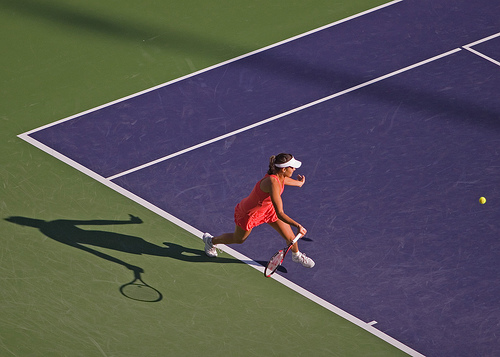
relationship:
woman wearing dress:
[181, 141, 333, 287] [231, 172, 291, 235]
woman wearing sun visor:
[181, 141, 333, 287] [272, 152, 311, 170]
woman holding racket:
[181, 141, 333, 287] [253, 228, 309, 280]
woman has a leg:
[181, 141, 333, 287] [210, 215, 255, 251]